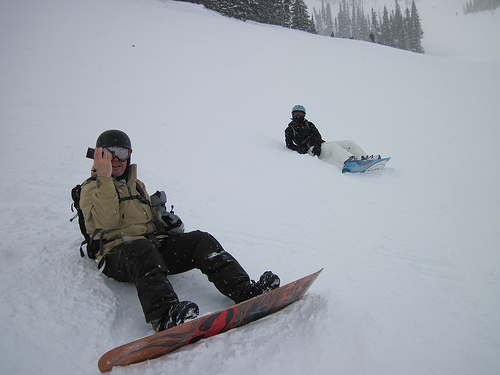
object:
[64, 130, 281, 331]
man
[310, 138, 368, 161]
pants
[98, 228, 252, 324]
pants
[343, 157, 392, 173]
board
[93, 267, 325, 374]
board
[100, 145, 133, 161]
goggles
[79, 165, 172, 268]
jacket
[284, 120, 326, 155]
jacket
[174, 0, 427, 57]
trees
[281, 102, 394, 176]
man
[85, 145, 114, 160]
phone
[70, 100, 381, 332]
together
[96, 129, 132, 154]
helmet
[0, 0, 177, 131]
snow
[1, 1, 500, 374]
picture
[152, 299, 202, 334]
boot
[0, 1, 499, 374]
ground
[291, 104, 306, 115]
helmet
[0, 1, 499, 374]
slope